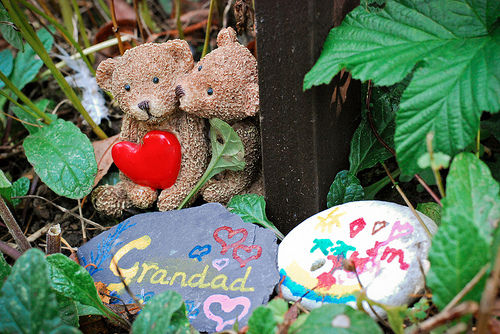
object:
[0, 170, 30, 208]
leaves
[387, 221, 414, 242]
heart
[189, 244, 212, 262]
heart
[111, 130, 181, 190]
heart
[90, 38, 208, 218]
bear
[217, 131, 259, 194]
legs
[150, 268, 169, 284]
words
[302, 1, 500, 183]
leaf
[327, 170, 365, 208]
leaf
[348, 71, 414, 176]
leaf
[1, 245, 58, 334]
leaf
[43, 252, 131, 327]
leaf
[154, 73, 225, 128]
wall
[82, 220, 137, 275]
blue writing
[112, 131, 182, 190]
symbol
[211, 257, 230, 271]
hearts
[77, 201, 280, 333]
ball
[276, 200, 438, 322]
painted rock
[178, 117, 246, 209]
green leaf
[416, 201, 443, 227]
leafs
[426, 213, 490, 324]
leaf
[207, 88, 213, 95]
eyes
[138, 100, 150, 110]
nose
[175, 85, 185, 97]
nose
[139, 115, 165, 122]
mouth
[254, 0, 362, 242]
post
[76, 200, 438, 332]
two rocks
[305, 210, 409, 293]
picture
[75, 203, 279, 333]
rock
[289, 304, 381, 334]
leaves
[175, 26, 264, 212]
bear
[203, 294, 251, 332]
heart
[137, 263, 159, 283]
words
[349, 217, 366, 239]
words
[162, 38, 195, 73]
ears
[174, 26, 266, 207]
stuffed animal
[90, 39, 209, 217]
stuffed animal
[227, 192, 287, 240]
leaf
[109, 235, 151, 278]
writing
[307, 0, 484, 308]
plant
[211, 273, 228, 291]
word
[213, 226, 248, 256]
heart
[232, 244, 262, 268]
heart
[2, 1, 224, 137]
grass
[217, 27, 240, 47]
ear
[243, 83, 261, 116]
ear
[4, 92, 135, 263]
dirt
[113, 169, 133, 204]
leg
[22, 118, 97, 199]
grass leaf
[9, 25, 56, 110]
grass leaf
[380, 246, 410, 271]
word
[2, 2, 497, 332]
ground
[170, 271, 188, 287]
word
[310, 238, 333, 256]
word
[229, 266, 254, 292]
word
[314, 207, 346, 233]
word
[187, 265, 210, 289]
word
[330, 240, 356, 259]
word